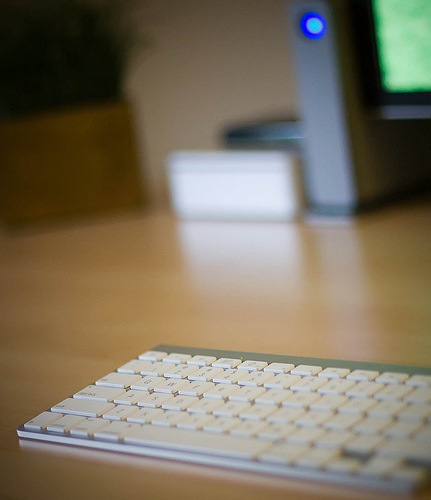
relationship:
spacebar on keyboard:
[109, 421, 274, 472] [8, 343, 429, 495]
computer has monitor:
[358, 57, 428, 138] [352, 2, 429, 129]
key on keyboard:
[134, 336, 167, 364] [8, 343, 429, 495]